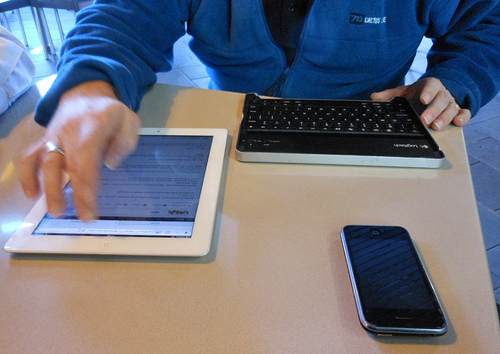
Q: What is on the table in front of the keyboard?
A: A cell phone.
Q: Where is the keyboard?
A: On the table.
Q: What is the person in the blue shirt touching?
A: An ipad.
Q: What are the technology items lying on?
A: A tan colored table.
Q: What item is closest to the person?
A: A black, wireless tablet keyboard.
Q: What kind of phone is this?
A: A black iphone.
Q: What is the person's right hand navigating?
A: An i-pad.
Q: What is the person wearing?
A: A fleece blue jacket.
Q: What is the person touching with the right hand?
A: A tablet.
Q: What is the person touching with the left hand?
A: A keyboard.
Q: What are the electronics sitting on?
A: A table.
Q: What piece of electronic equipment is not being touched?
A: The cellular phone.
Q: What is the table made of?
A: Wood.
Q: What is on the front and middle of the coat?
A: A zipper.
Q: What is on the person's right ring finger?
A: A diamond ring.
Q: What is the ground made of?
A: Brick.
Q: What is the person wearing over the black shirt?
A: A blue coat.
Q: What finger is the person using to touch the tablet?
A: Her right middle finger.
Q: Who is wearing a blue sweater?
A: A woman.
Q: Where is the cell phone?
A: On a desk.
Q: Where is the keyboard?
A: On the desk.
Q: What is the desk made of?
A: Wood.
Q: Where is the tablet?
A: On a desk.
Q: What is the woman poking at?
A: A tablet.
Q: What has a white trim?
A: The tablet.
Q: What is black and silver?
A: A cell phone.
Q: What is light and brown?
A: The table.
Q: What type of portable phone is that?
A: Cell phone.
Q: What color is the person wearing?
A: Blue.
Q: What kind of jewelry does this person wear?
A: A ring.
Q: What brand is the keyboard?
A: Logitech.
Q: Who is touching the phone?
A: No one.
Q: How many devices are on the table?
A: Three.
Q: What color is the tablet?
A: White.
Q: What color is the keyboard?
A: Black.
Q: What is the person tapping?
A: The tablet.